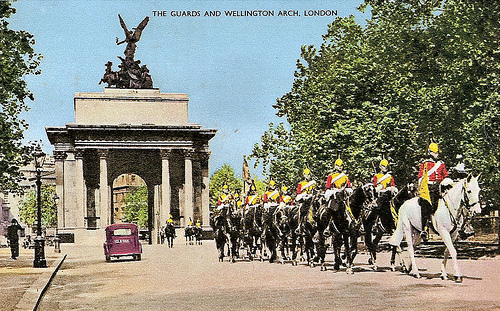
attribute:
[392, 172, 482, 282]
horse — white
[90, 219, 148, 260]
automobile — vintage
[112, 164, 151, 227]
door — open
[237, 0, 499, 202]
trees — leafy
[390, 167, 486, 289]
horse — white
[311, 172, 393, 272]
black horse — line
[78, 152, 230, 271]
arch — wellington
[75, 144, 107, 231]
column — stone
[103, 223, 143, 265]
car — red 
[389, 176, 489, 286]
horse — the soldier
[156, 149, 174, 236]
stone column — structure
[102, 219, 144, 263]
car — red 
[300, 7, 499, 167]
leaves — green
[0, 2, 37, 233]
leaves — green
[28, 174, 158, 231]
leaves — green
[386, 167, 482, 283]
horse — white 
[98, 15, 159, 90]
statue — angellic, winged